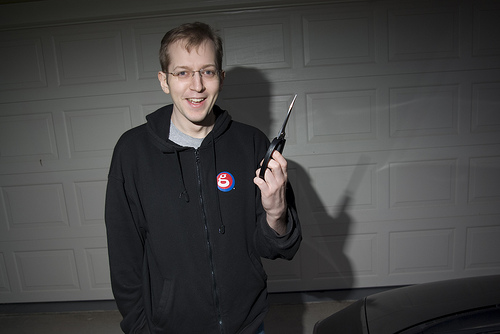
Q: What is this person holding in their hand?
A: Scissors.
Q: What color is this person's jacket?
A: Black.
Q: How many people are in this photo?
A: One.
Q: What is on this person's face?
A: Glasses.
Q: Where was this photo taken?
A: Outside a garage, at night.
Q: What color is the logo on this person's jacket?
A: Red, white, and blue.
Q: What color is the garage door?
A: White.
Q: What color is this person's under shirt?
A: Gray.